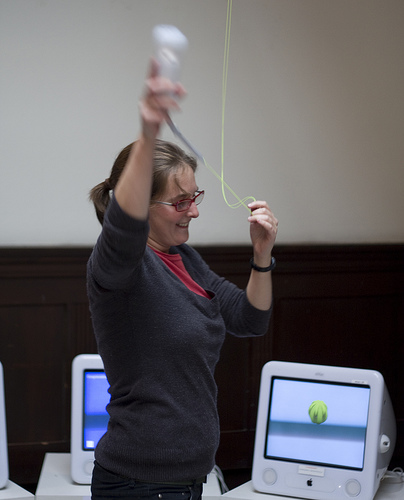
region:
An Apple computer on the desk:
[249, 356, 398, 498]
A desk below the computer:
[229, 460, 403, 497]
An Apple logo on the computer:
[305, 477, 311, 486]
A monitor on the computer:
[266, 371, 366, 467]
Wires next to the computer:
[385, 465, 402, 486]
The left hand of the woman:
[242, 198, 281, 241]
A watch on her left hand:
[249, 255, 276, 270]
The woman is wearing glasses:
[146, 191, 202, 207]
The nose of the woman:
[183, 199, 198, 218]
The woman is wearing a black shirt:
[83, 207, 267, 486]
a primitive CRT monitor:
[251, 360, 387, 499]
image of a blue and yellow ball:
[307, 397, 329, 426]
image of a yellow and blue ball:
[308, 397, 331, 422]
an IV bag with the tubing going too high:
[148, 0, 257, 214]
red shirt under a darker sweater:
[147, 243, 210, 297]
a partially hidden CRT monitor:
[69, 352, 111, 484]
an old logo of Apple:
[304, 476, 313, 490]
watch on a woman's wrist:
[250, 256, 276, 274]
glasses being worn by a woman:
[147, 184, 207, 211]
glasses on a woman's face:
[152, 186, 204, 210]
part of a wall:
[358, 317, 375, 333]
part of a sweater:
[161, 436, 174, 454]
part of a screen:
[306, 450, 313, 461]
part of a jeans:
[123, 481, 130, 489]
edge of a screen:
[262, 429, 269, 444]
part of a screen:
[81, 410, 89, 423]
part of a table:
[231, 484, 237, 496]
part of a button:
[349, 473, 357, 489]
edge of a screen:
[296, 394, 304, 406]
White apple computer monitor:
[244, 358, 398, 496]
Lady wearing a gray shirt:
[75, 106, 253, 477]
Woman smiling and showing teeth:
[70, 102, 274, 314]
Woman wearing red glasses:
[81, 158, 256, 271]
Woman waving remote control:
[101, 16, 283, 239]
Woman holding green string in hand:
[58, 23, 316, 316]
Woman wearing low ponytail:
[58, 22, 307, 358]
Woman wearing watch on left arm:
[40, 14, 321, 365]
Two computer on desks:
[9, 329, 400, 492]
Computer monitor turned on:
[226, 329, 397, 498]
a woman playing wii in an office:
[41, 13, 392, 493]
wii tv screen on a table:
[245, 337, 398, 494]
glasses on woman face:
[159, 171, 222, 224]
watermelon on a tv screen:
[303, 386, 329, 431]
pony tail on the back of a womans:
[75, 159, 130, 229]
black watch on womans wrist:
[243, 237, 286, 275]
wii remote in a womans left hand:
[136, 19, 275, 221]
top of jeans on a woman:
[93, 454, 240, 498]